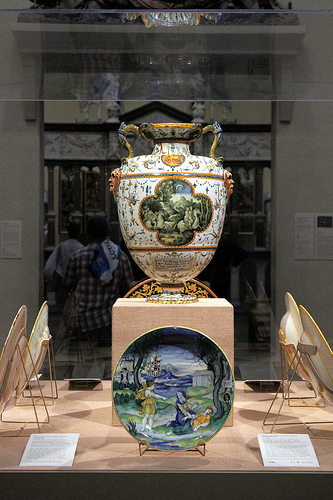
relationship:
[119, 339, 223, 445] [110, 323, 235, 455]
painting drawn on plate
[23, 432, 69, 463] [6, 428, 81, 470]
text printed on paper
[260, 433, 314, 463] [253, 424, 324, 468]
text printed on paper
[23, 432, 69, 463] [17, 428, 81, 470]
text printed on paper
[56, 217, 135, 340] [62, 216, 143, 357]
reflection showing gentleman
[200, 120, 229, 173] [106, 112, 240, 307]
handle attached to vase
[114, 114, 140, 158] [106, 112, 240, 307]
handle attached to vase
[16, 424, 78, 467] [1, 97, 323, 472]
placards lying in front of display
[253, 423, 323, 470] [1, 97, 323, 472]
placards lying in front of display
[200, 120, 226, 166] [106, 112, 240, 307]
handle attached to vase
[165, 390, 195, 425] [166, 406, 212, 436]
person reaching out to person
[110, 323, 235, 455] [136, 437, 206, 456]
plate sitting on top of rack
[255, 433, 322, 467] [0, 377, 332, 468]
paper lying on top of display table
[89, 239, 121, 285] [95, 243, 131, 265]
jersey hanging over shoulder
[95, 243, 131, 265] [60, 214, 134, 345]
shoulder belonging to man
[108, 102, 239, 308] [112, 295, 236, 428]
vase sitting on block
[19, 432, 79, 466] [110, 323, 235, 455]
paper next to plate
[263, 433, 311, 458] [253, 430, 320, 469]
text on paper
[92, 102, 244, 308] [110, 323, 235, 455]
vase above plate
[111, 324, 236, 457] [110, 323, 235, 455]
artwork painted on plate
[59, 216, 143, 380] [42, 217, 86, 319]
gentleman helping man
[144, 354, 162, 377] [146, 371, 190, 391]
ship on waters